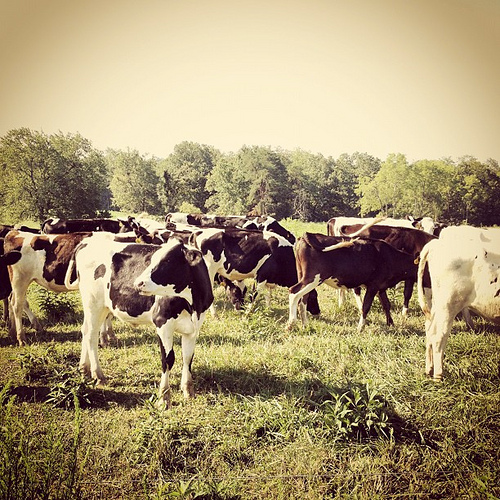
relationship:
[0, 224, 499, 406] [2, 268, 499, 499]
cows in field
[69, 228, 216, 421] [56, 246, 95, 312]
cow has tail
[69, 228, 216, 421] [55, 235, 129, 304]
cow has rear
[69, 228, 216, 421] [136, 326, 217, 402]
cow has leg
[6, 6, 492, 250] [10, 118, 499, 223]
background has trees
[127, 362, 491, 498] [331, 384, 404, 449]
grass has weeds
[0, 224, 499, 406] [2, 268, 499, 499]
cows in pasture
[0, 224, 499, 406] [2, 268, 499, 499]
cows on pasture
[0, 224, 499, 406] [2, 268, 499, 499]
cows on field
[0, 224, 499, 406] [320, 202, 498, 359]
cows in group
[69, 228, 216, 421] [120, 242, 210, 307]
cow has head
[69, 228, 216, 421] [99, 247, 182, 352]
cow has body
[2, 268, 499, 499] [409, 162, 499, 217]
field has shrubs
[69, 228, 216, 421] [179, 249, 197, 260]
cow has tag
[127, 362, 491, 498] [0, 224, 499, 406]
grass in front of cows